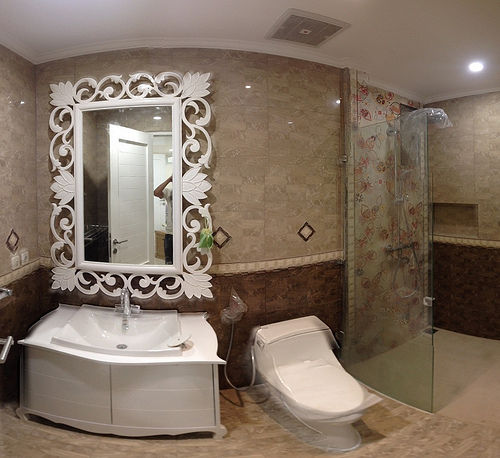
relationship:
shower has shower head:
[348, 68, 499, 423] [427, 109, 452, 130]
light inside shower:
[466, 58, 483, 72] [348, 68, 499, 423]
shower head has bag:
[427, 109, 452, 130] [401, 105, 451, 158]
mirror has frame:
[48, 73, 213, 299] [50, 83, 214, 299]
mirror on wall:
[48, 73, 213, 299] [37, 48, 344, 391]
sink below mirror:
[23, 289, 226, 366] [48, 73, 213, 299]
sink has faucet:
[23, 289, 226, 366] [116, 290, 139, 317]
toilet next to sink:
[250, 313, 382, 452] [23, 289, 226, 366]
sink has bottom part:
[23, 289, 226, 366] [16, 344, 226, 441]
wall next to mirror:
[37, 48, 344, 391] [48, 73, 213, 299]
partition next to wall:
[343, 114, 434, 413] [37, 48, 344, 391]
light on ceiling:
[466, 58, 483, 72] [1, 3, 498, 107]